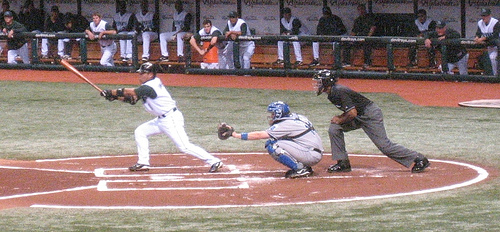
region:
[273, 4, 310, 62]
a person is sitting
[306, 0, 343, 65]
a person is sitting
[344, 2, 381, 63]
a person is sitting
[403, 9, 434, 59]
a person is sitting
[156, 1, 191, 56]
a person is sitting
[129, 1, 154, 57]
a person is sitting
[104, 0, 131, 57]
a person is sitting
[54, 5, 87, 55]
a person is sitting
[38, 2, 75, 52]
a person is sitting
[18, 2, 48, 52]
a person is sitting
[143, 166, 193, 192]
Home plate on baseball field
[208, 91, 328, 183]
Baseball catcher with glove out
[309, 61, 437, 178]
Baseball umpire crouching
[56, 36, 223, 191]
Baseball player swinging bat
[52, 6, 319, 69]
Baseball players watching game from dugout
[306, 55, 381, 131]
Baseball umpire wearing a helmet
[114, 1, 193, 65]
Baseball players sitting in the dugout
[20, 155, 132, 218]
Chalk lines on a baseball field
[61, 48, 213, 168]
Baseball player with a bat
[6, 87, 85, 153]
Green grass on a baseball field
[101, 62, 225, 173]
Baseball batter swinging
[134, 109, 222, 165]
White pants on baseball player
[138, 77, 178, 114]
White jersey on baseball player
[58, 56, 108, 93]
Brown bat held by batter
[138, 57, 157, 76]
Black helmet on baseball players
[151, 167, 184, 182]
Home plate on baseball field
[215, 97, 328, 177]
Baseball in squat behind home plate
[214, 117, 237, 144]
Brown mitt used by baseball catcher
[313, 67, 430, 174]
Home plate umpire at a baseball game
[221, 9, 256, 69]
Baseball player watching game from dugout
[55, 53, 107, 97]
RED METAL BASEBALL BAT IN PLAYERS HANDS.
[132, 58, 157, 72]
BLACK BASEBALL HELMET ON PLAYERS HEAD.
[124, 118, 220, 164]
WHITE BASEBALL PANTS ON PLAYER.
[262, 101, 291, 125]
BLUE CATCHERS MASK.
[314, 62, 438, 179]
UMPIRE BENT OVER WATCHING PLAYERS.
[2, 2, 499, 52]
BASEBALL PLAYERS IN DUG OUT.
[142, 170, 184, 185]
HOME PLATE ON BASEBALL FIELD.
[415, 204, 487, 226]
GREEN BASEBALL FIELD GRASS.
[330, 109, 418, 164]
GREY UMPIRE PANTS ON MAN.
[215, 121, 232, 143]
BLACK CATCHERS MIT ON PLAYER.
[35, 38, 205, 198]
A batter at home plate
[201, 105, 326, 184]
A catch with his glove raised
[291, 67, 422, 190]
a umpire dressed in black and gray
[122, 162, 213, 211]
Home plate of a baseball field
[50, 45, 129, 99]
A wooden baseball bat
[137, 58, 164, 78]
a baseball helmet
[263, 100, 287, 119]
a catches mask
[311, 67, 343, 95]
The umpire has a face mask.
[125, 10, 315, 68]
Group of baseball players watching the game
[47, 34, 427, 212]
A baseball game in progress